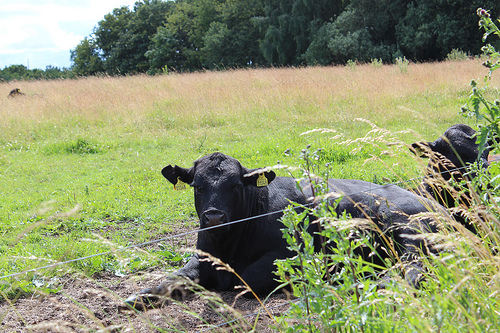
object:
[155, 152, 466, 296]
cow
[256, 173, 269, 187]
tag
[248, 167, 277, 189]
ear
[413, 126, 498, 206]
cow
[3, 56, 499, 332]
pasture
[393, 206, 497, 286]
flowers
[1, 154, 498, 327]
fence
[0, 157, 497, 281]
wire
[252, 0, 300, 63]
trees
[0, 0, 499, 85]
background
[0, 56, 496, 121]
grass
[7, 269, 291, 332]
dirt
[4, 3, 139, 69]
sky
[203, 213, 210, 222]
nostrils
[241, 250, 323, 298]
legs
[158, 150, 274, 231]
head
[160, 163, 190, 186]
ear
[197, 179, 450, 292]
body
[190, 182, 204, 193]
eyes